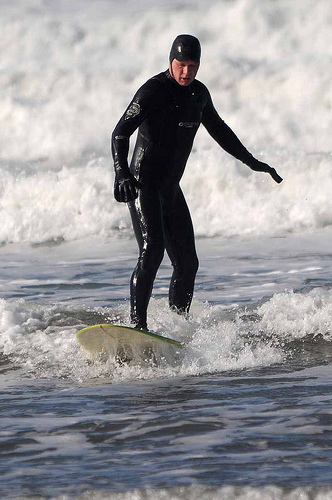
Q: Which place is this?
A: It is an ocean.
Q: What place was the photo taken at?
A: It was taken at the ocean.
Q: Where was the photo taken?
A: It was taken at the ocean.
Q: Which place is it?
A: It is an ocean.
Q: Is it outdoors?
A: Yes, it is outdoors.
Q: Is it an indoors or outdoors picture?
A: It is outdoors.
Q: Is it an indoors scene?
A: No, it is outdoors.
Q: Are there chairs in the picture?
A: No, there are no chairs.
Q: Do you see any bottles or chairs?
A: No, there are no chairs or bottles.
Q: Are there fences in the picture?
A: No, there are no fences.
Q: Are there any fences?
A: No, there are no fences.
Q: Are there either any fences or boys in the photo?
A: No, there are no fences or boys.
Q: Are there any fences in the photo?
A: No, there are no fences.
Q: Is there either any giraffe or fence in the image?
A: No, there are no fences or giraffes.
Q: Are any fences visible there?
A: No, there are no fences.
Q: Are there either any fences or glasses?
A: No, there are no fences or glasses.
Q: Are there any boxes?
A: No, there are no boxes.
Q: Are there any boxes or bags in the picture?
A: No, there are no boxes or bags.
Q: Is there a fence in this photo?
A: No, there are no fences.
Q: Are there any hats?
A: Yes, there is a hat.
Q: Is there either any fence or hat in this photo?
A: Yes, there is a hat.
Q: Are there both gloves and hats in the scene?
A: Yes, there are both a hat and gloves.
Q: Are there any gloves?
A: Yes, there are gloves.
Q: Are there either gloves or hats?
A: Yes, there are gloves.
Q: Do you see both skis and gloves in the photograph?
A: No, there are gloves but no skis.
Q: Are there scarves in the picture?
A: No, there are no scarves.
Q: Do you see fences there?
A: No, there are no fences.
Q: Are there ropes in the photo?
A: No, there are no ropes.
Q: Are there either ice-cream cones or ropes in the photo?
A: No, there are no ropes or ice-cream cones.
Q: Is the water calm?
A: Yes, the water is calm.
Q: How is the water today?
A: The water is calm.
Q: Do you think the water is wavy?
A: No, the water is calm.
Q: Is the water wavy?
A: No, the water is calm.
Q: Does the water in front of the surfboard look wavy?
A: No, the water is calm.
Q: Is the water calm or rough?
A: The water is calm.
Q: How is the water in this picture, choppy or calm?
A: The water is calm.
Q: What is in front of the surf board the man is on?
A: The water is in front of the surfboard.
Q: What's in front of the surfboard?
A: The water is in front of the surfboard.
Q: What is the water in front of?
A: The water is in front of the surfboard.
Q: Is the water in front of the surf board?
A: Yes, the water is in front of the surf board.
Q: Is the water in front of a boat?
A: No, the water is in front of the surf board.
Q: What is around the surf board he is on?
A: The water is around the surfboard.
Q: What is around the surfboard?
A: The water is around the surfboard.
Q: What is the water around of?
A: The water is around the surf board.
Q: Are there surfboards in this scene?
A: Yes, there is a surfboard.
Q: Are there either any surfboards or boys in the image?
A: Yes, there is a surfboard.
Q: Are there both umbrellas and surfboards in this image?
A: No, there is a surfboard but no umbrellas.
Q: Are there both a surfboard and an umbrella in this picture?
A: No, there is a surfboard but no umbrellas.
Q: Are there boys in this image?
A: No, there are no boys.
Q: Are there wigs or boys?
A: No, there are no boys or wigs.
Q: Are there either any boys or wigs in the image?
A: No, there are no boys or wigs.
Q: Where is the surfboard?
A: The surfboard is in the water.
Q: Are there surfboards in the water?
A: Yes, there is a surfboard in the water.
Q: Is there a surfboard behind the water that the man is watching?
A: Yes, there is a surfboard behind the water.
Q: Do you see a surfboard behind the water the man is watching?
A: Yes, there is a surfboard behind the water.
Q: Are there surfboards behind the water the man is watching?
A: Yes, there is a surfboard behind the water.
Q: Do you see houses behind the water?
A: No, there is a surfboard behind the water.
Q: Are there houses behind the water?
A: No, there is a surfboard behind the water.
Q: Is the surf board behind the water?
A: Yes, the surf board is behind the water.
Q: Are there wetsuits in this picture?
A: Yes, there is a wetsuit.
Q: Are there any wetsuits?
A: Yes, there is a wetsuit.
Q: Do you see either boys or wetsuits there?
A: Yes, there is a wetsuit.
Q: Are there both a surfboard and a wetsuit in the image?
A: Yes, there are both a wetsuit and a surfboard.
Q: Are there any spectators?
A: No, there are no spectators.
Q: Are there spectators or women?
A: No, there are no spectators or women.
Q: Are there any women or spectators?
A: No, there are no spectators or women.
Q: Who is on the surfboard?
A: The man is on the surfboard.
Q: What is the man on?
A: The man is on the surfboard.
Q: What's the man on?
A: The man is on the surfboard.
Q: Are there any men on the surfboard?
A: Yes, there is a man on the surfboard.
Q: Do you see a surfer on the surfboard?
A: No, there is a man on the surfboard.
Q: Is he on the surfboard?
A: Yes, the man is on the surfboard.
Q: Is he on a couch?
A: No, the man is on the surfboard.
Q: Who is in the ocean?
A: The man is in the ocean.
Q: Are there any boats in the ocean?
A: No, there is a man in the ocean.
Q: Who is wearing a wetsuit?
A: The man is wearing a wetsuit.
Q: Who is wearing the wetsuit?
A: The man is wearing a wetsuit.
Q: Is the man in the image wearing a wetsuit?
A: Yes, the man is wearing a wetsuit.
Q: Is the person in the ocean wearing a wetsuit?
A: Yes, the man is wearing a wetsuit.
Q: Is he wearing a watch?
A: No, the man is wearing a wetsuit.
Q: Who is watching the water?
A: The man is watching the water.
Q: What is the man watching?
A: The man is watching the water.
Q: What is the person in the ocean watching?
A: The man is watching the water.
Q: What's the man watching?
A: The man is watching the water.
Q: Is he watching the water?
A: Yes, the man is watching the water.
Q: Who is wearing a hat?
A: The man is wearing a hat.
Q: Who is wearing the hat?
A: The man is wearing a hat.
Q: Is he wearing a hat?
A: Yes, the man is wearing a hat.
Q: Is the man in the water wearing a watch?
A: No, the man is wearing a hat.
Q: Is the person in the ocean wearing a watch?
A: No, the man is wearing a hat.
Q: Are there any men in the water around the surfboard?
A: Yes, there is a man in the water.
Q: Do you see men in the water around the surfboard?
A: Yes, there is a man in the water.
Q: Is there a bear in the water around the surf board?
A: No, there is a man in the water.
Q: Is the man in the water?
A: Yes, the man is in the water.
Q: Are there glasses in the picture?
A: No, there are no glasses.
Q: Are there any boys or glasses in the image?
A: No, there are no glasses or boys.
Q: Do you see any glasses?
A: No, there are no glasses.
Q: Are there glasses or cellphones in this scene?
A: No, there are no glasses or cellphones.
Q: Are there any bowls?
A: No, there are no bowls.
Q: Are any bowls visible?
A: No, there are no bowls.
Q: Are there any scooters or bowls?
A: No, there are no bowls or scooters.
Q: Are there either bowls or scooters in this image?
A: No, there are no bowls or scooters.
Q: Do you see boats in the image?
A: No, there are no boats.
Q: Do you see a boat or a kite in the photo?
A: No, there are no boats or kites.